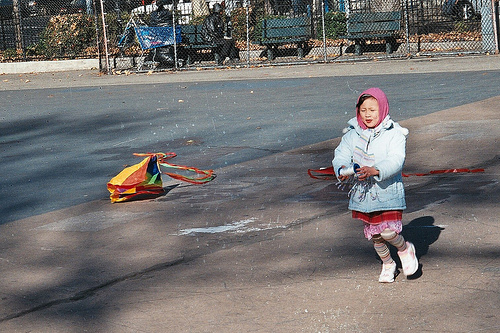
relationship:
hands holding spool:
[335, 159, 378, 188] [336, 162, 358, 184]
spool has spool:
[336, 162, 358, 184] [338, 164, 359, 177]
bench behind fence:
[257, 13, 316, 65] [8, 0, 497, 75]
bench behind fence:
[346, 9, 405, 55] [8, 0, 497, 75]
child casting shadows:
[331, 88, 419, 284] [0, 111, 499, 332]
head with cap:
[355, 86, 393, 132] [355, 87, 390, 129]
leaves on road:
[105, 93, 441, 262] [0, 57, 500, 333]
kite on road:
[104, 144, 218, 209] [0, 57, 500, 333]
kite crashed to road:
[104, 144, 218, 209] [0, 57, 500, 333]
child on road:
[330, 83, 426, 288] [0, 57, 500, 333]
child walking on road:
[330, 83, 426, 288] [0, 57, 500, 333]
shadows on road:
[9, 87, 495, 318] [0, 57, 500, 333]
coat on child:
[331, 114, 411, 213] [330, 83, 426, 288]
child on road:
[331, 88, 419, 284] [6, 69, 499, 329]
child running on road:
[331, 88, 419, 284] [6, 69, 499, 329]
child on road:
[331, 88, 419, 284] [0, 57, 500, 333]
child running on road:
[331, 88, 419, 284] [0, 57, 500, 333]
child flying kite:
[331, 88, 419, 284] [104, 144, 218, 209]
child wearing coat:
[331, 88, 419, 284] [330, 117, 409, 212]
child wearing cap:
[331, 88, 419, 284] [355, 87, 390, 129]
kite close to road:
[104, 144, 218, 209] [0, 57, 500, 333]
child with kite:
[331, 88, 419, 284] [104, 144, 218, 209]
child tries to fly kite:
[331, 88, 419, 284] [104, 144, 218, 209]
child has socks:
[331, 88, 419, 284] [369, 224, 407, 263]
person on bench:
[197, 2, 241, 62] [137, 19, 224, 70]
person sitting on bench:
[197, 2, 241, 62] [137, 19, 224, 70]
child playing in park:
[331, 88, 419, 284] [5, 4, 500, 327]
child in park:
[331, 88, 419, 284] [5, 4, 500, 327]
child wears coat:
[331, 88, 419, 284] [330, 117, 409, 212]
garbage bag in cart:
[145, 7, 180, 27] [120, 15, 183, 66]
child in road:
[331, 88, 419, 284] [6, 69, 499, 329]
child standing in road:
[331, 88, 419, 284] [6, 69, 499, 329]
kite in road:
[104, 144, 218, 209] [6, 69, 499, 329]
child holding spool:
[331, 88, 419, 284] [338, 164, 359, 177]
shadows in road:
[0, 111, 499, 332] [6, 69, 499, 329]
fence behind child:
[8, 0, 497, 75] [331, 88, 419, 284]